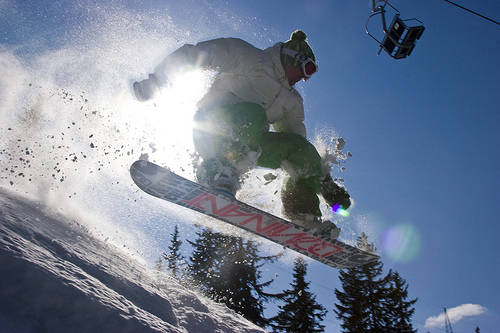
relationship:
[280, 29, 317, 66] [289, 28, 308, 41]
beanie has a pom pom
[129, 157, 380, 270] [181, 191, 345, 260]
snowboard has text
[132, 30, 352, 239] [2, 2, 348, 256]
man kicking up snow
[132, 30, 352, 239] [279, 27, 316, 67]
man wearing a cap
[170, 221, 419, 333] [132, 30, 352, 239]
trees are behind man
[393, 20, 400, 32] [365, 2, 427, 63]
sticker on back of ski lift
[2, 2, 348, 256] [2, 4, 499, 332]
snow flying in air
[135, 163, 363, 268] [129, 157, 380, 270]
design on snowboard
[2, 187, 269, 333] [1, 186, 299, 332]
snow on ground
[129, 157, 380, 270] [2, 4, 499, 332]
snowboard in air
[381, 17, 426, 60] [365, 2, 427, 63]
chair on ski lift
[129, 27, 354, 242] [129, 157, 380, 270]
man riding on a snowboard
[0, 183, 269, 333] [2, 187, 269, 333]
hill covered with snow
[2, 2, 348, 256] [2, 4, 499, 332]
snow in air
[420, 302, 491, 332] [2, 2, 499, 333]
cloud sitting in sky